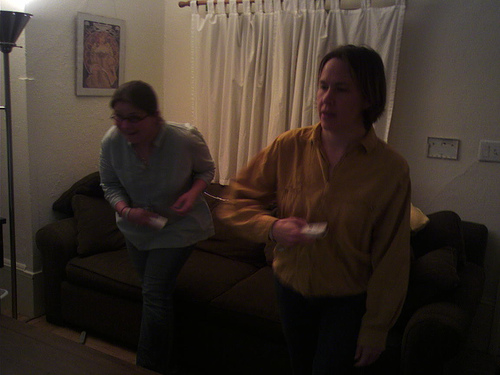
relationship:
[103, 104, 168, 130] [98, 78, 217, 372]
glasses on woman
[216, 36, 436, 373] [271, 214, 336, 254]
man holding controller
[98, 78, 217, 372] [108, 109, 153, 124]
woman wearing glasses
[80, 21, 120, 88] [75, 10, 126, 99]
artwork with matting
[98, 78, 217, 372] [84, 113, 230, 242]
woman wearing shirt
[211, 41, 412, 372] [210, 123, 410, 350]
woman wearing shirt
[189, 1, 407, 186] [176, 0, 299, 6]
curtain hanging off rod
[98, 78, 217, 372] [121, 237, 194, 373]
woman wearing jeans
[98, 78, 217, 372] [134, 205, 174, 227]
woman holding controller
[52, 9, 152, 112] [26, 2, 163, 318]
picture on wall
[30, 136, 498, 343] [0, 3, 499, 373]
couch in living room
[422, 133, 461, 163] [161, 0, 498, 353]
plaque on wall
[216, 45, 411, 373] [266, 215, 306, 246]
man has hand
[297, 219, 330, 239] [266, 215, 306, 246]
game controller in hand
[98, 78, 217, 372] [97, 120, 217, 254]
woman wearing t shirt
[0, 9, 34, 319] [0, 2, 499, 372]
lamp in room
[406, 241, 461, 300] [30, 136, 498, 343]
pillow on couch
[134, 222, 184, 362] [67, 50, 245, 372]
foot of woman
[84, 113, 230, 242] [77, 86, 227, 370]
shirt of woman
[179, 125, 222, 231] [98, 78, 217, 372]
hand of woman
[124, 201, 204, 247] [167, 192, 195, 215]
controller in hand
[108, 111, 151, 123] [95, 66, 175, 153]
glasses on face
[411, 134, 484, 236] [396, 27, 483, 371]
switch on wall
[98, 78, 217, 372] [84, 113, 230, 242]
woman wearing a shirt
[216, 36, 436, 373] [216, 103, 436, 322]
man wearing a shirt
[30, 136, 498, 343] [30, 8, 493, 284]
couch against wall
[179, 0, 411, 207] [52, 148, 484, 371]
curtains behind couch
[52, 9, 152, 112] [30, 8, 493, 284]
picture on wall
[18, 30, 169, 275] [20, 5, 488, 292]
wall on side of building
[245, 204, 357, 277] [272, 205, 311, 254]
remote in hand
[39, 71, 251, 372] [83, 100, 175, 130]
lady wearing glasses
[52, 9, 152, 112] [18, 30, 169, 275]
picture on wall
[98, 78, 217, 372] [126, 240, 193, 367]
woman wearing jeans